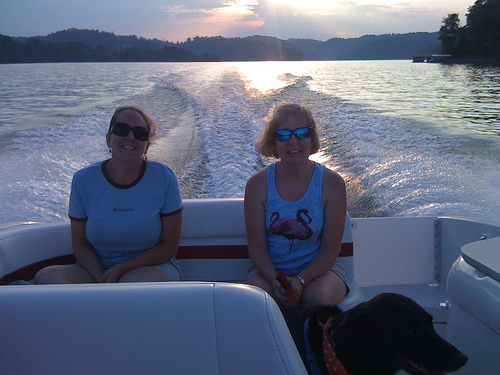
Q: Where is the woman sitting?
A: On a boat.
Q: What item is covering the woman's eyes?
A: Sunglasses.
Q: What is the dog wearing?
A: A red scarf.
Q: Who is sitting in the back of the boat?
A: Two women.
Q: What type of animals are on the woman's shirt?
A: Flamingos.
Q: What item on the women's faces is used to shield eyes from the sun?
A: Sunglasses.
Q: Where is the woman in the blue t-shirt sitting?
A: In a boat.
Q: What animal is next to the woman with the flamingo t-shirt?
A: A dog.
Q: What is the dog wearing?
A: A red bandanna.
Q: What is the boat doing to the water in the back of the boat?
A: Making waves.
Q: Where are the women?
A: On a boat.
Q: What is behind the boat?
A: The wake.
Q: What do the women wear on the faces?
A: Sunglasses.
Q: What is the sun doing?
A: Setting.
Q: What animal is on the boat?
A: Dog.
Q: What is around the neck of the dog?
A: Collar.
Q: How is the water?
A: Calm.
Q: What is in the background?
A: Mountains.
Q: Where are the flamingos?
A: On the shirt.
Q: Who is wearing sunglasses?
A: Two ladies.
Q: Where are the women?
A: On a boat.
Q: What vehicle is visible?
A: Boat.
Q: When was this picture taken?
A: Sunset.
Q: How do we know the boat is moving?
A: Wake.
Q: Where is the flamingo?
A: On the right woman's shirt.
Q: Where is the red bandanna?
A: Around the dog's neck.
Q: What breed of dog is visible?
A: Chocolate Lab.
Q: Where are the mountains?
A: Other side of the lake.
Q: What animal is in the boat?
A: A Dog.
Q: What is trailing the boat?
A: Waves.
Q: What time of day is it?
A: Dusk.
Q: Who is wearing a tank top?
A: Woman on the right.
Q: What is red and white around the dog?
A: Bandana.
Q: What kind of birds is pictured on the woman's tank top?
A: Pelicans.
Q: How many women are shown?
A: 2.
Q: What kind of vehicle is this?
A: Boat.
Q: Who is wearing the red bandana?
A: Dog.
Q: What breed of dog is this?
A: Labrador Retriever.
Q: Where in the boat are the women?
A: Back.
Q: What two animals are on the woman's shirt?
A: Flamingos.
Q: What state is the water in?
A: Liquid.